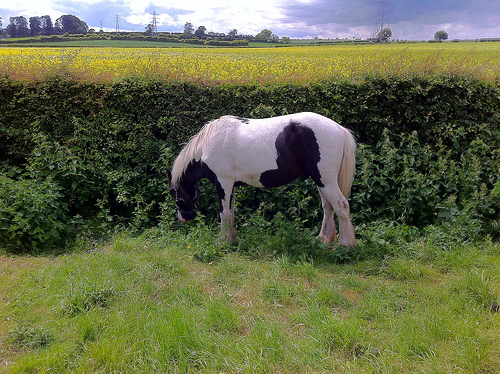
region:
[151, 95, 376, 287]
A horse is outside.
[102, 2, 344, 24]
Blue sky with clouds.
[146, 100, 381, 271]
The horse is white with black spots.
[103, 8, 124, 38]
A power pole in the distance.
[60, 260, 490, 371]
Grass near the horse.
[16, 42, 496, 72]
A field in the distance.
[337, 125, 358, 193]
The horse has a tail.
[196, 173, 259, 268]
The horse has two front legs.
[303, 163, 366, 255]
The horse has two back legs.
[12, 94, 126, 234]
Green leaves on a plant.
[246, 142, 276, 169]
stomach of a horse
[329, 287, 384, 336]
part of a grass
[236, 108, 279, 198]
edge of a stomach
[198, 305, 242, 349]
part of a train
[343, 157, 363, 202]
part of a train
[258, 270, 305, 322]
part of some grass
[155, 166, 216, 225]
part of a horse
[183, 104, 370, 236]
white and black horse grazing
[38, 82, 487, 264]
thick dark green bushes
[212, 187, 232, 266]
leg of grazing horse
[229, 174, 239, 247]
leg of grazing horse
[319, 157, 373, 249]
leg of grazing horse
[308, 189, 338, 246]
leg of grazing horse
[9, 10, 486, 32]
green trees in distance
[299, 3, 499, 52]
dark storm clouds moving in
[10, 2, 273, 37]
sun shining in behind clouds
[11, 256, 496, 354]
luscious green grass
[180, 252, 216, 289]
part of some grass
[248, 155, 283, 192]
stomach of a horse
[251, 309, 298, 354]
part of a ground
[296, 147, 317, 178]
part of a black spot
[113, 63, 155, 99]
edge of a bush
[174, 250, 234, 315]
part of a grass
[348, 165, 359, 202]
edge of a tail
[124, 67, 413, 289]
Horse grazing in field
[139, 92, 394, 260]
Horse is black and white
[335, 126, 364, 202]
Long white tail hair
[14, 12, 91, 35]
Group of trees in background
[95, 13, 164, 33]
String of power lines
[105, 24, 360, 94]
Yellow flowers in the field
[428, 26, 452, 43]
Small tree in the background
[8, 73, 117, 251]
Weeds in front of field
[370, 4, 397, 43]
Tall dead tree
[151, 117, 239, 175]
white hair on mane